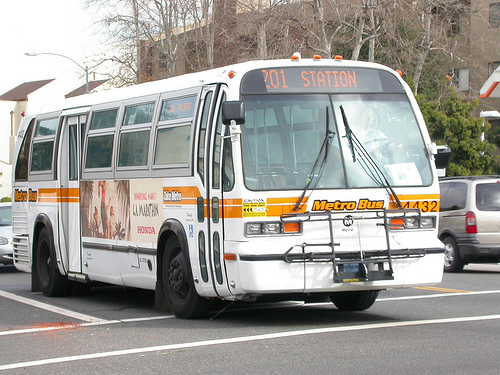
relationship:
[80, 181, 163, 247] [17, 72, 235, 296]
advertisement on side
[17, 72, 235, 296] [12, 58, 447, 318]
side of bus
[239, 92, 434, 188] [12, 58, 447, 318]
windshield of bus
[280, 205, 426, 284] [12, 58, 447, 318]
bike rack in front of bus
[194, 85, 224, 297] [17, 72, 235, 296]
door on side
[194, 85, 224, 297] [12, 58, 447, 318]
door on bus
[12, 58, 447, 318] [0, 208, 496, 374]
bus on street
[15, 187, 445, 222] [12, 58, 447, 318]
stripe around bus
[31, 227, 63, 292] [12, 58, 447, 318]
wheel of bus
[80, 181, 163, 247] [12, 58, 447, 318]
advertisement on side of bus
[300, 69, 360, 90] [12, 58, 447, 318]
destination on front of bus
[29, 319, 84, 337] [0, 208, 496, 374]
spill on street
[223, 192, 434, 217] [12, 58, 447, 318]
lines are on bus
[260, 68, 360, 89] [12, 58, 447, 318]
201 station on front of bus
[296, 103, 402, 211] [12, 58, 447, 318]
windshield wipers are on front of bus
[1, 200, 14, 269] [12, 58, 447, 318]
car behind bus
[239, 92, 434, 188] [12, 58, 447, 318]
windshield on front of bus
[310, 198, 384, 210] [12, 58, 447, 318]
logo on front of bus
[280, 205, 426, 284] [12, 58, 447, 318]
bike rack on front of bus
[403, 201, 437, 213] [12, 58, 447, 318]
numbering on front of bus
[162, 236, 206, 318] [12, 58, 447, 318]
tire on bus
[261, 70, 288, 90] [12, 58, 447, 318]
number on bus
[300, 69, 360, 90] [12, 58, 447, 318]
station on bus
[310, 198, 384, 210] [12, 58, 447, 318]
metro bus on front of bus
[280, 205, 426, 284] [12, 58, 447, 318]
bike rack on bus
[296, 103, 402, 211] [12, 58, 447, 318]
windshield wipers are on bus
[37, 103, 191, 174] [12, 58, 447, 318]
windows are on bus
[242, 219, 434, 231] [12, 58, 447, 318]
headlights of bus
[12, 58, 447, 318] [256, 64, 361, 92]
bus heading to 201 station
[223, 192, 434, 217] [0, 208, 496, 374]
lines are on road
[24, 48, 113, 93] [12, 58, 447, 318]
light pole behind bus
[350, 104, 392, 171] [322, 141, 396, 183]
bus driver in seat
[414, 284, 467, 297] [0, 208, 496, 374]
line in road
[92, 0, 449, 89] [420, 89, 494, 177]
trees without leaves